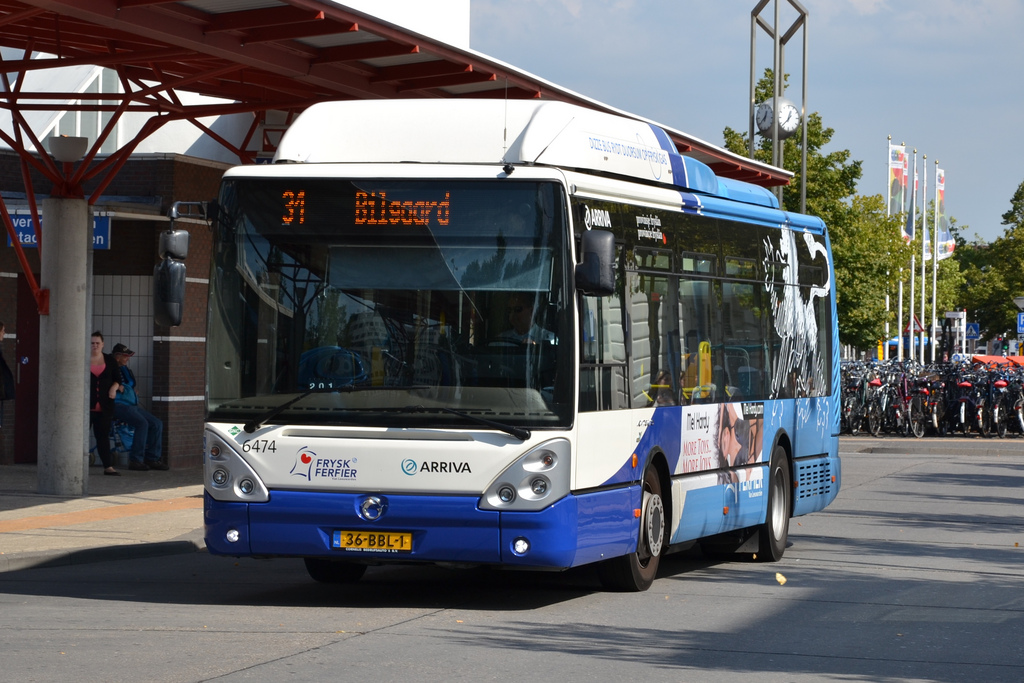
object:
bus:
[202, 97, 842, 591]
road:
[0, 437, 1024, 683]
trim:
[203, 422, 646, 572]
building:
[3, 0, 800, 500]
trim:
[681, 158, 832, 237]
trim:
[517, 165, 689, 215]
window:
[208, 175, 573, 427]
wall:
[91, 208, 151, 468]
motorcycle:
[988, 355, 1024, 437]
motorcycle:
[952, 357, 972, 432]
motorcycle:
[863, 363, 885, 436]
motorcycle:
[948, 351, 975, 434]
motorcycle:
[956, 350, 969, 432]